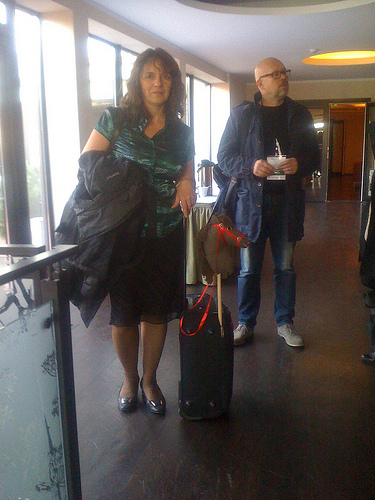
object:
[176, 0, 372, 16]
hole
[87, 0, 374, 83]
ceiling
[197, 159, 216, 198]
coffee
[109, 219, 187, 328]
skirt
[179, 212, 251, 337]
pony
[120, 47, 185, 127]
hair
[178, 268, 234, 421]
suitcase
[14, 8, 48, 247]
panel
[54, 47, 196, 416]
lady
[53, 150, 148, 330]
coat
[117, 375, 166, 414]
shoes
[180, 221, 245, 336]
ribbon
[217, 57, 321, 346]
man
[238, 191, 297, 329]
jeans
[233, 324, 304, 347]
white shoes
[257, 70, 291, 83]
glasses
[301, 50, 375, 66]
ceiling light